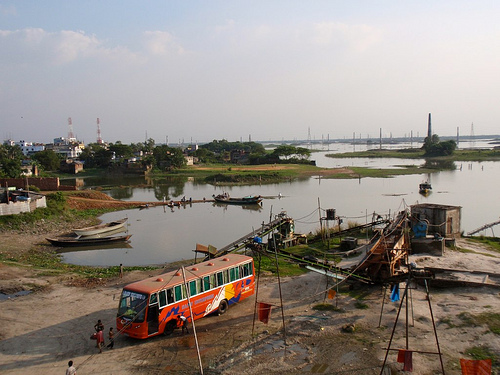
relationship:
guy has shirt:
[177, 311, 191, 331] [177, 314, 188, 324]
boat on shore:
[43, 229, 148, 254] [27, 201, 302, 299]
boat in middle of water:
[207, 184, 283, 211] [33, 135, 499, 287]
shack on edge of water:
[385, 197, 475, 245] [33, 135, 499, 287]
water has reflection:
[33, 135, 499, 287] [98, 176, 193, 207]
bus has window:
[113, 253, 261, 329] [188, 279, 198, 297]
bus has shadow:
[113, 253, 261, 329] [12, 305, 189, 360]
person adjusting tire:
[177, 311, 191, 331] [163, 316, 178, 339]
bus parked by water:
[113, 253, 261, 329] [33, 135, 499, 287]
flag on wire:
[389, 278, 405, 300] [383, 271, 426, 296]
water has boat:
[33, 135, 499, 287] [43, 229, 148, 254]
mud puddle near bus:
[145, 315, 374, 374] [113, 253, 261, 329]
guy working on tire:
[177, 311, 191, 331] [163, 316, 178, 339]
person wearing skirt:
[106, 321, 117, 348] [110, 335, 116, 347]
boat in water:
[207, 184, 283, 211] [33, 135, 499, 287]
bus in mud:
[113, 253, 261, 329] [22, 270, 292, 374]